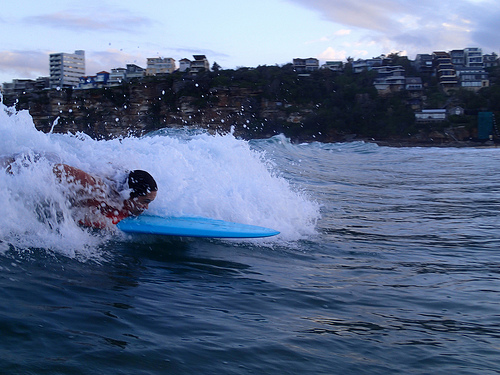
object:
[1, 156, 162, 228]
surfer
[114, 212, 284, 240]
surfboard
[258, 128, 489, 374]
water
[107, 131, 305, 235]
waves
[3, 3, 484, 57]
skies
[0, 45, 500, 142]
city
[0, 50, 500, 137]
buildings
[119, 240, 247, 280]
shadow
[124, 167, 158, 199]
black hair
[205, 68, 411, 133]
trees